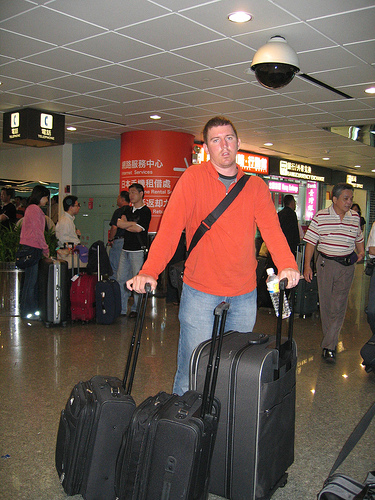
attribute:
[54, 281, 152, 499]
luggage — black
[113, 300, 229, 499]
luggage — black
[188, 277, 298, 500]
luggage — black, large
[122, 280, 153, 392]
handle — extended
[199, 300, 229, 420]
handle — extended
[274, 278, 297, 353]
handle — extended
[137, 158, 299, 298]
sweatshirt — orange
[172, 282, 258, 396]
jeans — faded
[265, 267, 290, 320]
bottle — plastic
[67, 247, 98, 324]
suitcase — red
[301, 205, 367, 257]
shirt — striped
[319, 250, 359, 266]
pouch — black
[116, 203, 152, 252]
shirt — black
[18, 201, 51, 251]
sweater — pink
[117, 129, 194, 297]
pillar — orange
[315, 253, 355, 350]
pants — brown, khaki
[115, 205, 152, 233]
arms — folded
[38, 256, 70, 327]
luggage — black